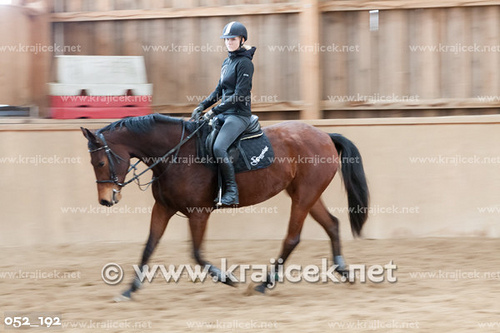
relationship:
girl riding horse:
[188, 19, 255, 212] [80, 115, 372, 303]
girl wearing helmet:
[188, 19, 255, 212] [220, 18, 252, 39]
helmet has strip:
[220, 18, 252, 39] [237, 34, 243, 49]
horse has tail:
[80, 115, 372, 303] [327, 131, 373, 242]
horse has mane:
[80, 115, 372, 303] [91, 114, 193, 134]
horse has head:
[80, 115, 372, 303] [73, 124, 133, 207]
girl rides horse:
[188, 19, 255, 212] [80, 115, 372, 303]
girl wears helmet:
[188, 19, 255, 212] [220, 18, 252, 39]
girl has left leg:
[188, 19, 255, 212] [211, 115, 248, 211]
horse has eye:
[80, 115, 372, 303] [93, 157, 109, 170]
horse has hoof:
[80, 115, 372, 303] [115, 278, 141, 300]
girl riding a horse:
[188, 19, 255, 212] [80, 115, 372, 303]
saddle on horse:
[188, 106, 264, 139] [80, 115, 372, 303]